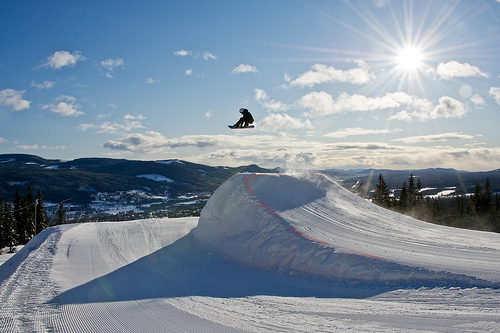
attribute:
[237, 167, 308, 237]
line — red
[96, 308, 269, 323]
snow — white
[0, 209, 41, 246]
trees — pine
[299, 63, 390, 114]
clouds — white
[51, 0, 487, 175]
day — sunny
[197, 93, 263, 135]
snowboarder — crouching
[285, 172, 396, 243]
slope — large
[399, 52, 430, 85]
sun — shining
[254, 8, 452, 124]
sky — blue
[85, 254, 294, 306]
shadow — triangular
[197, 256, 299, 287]
surface — flat